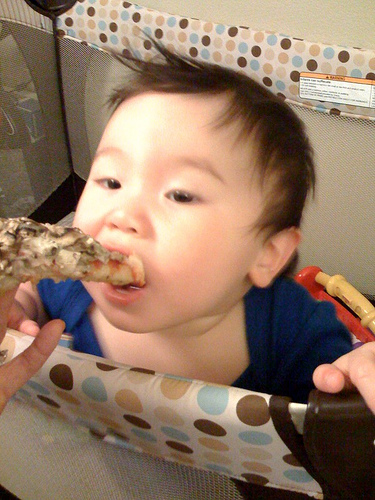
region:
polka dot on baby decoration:
[248, 47, 259, 58]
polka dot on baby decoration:
[235, 424, 267, 454]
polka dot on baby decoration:
[192, 418, 223, 436]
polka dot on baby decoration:
[237, 397, 270, 425]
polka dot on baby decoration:
[193, 389, 217, 415]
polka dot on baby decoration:
[114, 389, 142, 412]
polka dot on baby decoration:
[82, 383, 107, 406]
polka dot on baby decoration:
[50, 367, 74, 389]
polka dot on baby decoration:
[124, 417, 144, 429]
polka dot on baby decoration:
[145, 377, 184, 398]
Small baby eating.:
[2, 45, 368, 438]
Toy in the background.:
[292, 264, 373, 340]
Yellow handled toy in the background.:
[311, 266, 374, 336]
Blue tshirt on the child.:
[39, 264, 351, 396]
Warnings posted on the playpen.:
[296, 67, 374, 109]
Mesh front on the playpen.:
[3, 393, 299, 498]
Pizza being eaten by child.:
[3, 211, 151, 289]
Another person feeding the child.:
[2, 265, 76, 408]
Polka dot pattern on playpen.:
[1, 0, 373, 495]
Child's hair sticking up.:
[94, 30, 312, 294]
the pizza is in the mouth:
[11, 213, 143, 291]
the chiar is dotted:
[145, 389, 267, 485]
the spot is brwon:
[238, 394, 272, 431]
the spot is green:
[195, 385, 228, 413]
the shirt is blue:
[255, 298, 340, 384]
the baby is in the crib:
[39, 13, 364, 446]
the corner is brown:
[301, 397, 363, 497]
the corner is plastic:
[287, 401, 373, 484]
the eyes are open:
[90, 164, 212, 217]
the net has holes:
[44, 439, 126, 489]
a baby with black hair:
[4, 30, 366, 380]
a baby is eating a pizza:
[3, 37, 329, 359]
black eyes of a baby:
[85, 166, 207, 215]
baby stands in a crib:
[0, 1, 373, 498]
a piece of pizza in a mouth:
[3, 210, 156, 310]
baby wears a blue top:
[5, 47, 373, 419]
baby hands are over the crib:
[1, 35, 373, 415]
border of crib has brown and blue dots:
[41, 1, 373, 106]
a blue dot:
[192, 380, 235, 419]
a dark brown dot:
[234, 390, 274, 429]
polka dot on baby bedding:
[237, 428, 269, 446]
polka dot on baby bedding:
[192, 418, 226, 437]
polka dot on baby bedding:
[154, 400, 178, 427]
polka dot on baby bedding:
[114, 388, 147, 418]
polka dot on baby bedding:
[80, 374, 113, 405]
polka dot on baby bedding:
[47, 363, 74, 389]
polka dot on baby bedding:
[263, 48, 272, 59]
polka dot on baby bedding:
[304, 58, 315, 73]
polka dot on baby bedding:
[211, 39, 222, 51]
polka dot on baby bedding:
[177, 31, 189, 43]